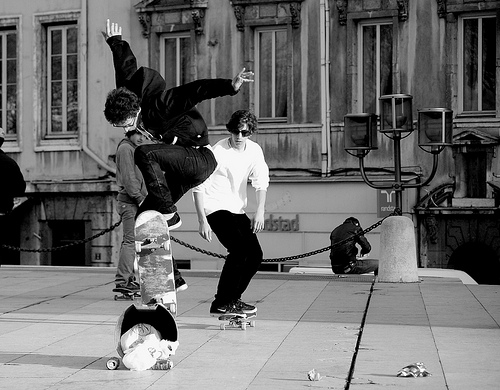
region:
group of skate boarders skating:
[93, 15, 275, 383]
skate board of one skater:
[121, 208, 183, 342]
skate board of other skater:
[216, 310, 261, 332]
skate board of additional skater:
[110, 281, 140, 300]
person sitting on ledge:
[319, 213, 381, 277]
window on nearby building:
[256, 13, 296, 126]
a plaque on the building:
[368, 183, 400, 215]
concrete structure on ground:
[371, 213, 421, 286]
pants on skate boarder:
[205, 208, 265, 300]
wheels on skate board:
[133, 235, 175, 259]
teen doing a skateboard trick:
[73, 5, 255, 372]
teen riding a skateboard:
[194, 88, 289, 331]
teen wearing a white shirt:
[201, 128, 269, 226]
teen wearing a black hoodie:
[106, 23, 253, 157]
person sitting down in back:
[316, 209, 386, 302]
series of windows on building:
[5, 18, 498, 150]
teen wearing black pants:
[203, 208, 274, 323]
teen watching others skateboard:
[110, 119, 157, 307]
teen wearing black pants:
[120, 132, 220, 217]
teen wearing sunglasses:
[231, 120, 258, 139]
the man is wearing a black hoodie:
[102, 35, 237, 139]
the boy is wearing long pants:
[204, 209, 265, 311]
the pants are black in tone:
[203, 210, 263, 307]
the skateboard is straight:
[130, 212, 185, 320]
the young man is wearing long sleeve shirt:
[196, 137, 269, 212]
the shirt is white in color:
[188, 138, 268, 216]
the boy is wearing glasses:
[228, 126, 252, 137]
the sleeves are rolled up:
[191, 161, 276, 196]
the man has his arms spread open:
[98, 18, 253, 110]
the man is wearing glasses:
[111, 118, 138, 129]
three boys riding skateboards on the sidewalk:
[63, 41, 288, 353]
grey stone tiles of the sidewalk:
[273, 290, 377, 362]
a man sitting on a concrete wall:
[324, 216, 394, 281]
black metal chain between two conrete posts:
[0, 223, 122, 259]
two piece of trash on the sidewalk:
[281, 358, 441, 388]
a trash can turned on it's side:
[107, 300, 199, 380]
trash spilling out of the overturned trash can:
[96, 328, 164, 375]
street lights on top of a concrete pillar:
[345, 89, 452, 218]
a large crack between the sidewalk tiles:
[331, 278, 379, 388]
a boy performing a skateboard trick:
[87, 35, 204, 312]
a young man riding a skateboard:
[206, 112, 276, 347]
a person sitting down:
[318, 207, 373, 282]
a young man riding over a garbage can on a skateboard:
[103, 32, 241, 332]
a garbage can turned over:
[93, 294, 179, 389]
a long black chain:
[1, 205, 401, 284]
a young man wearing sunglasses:
[226, 111, 258, 150]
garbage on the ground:
[291, 363, 459, 383]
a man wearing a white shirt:
[207, 106, 259, 226]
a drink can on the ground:
[95, 346, 125, 376]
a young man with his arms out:
[80, 38, 260, 148]